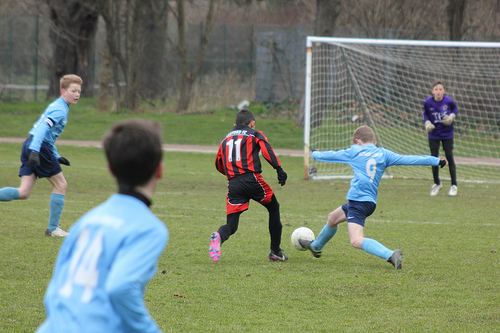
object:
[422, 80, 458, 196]
boy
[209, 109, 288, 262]
boy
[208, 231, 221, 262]
sole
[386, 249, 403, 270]
sole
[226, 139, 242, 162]
number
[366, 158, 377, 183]
number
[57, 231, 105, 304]
number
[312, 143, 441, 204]
jersey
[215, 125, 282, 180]
jersey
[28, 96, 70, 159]
jersey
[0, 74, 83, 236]
player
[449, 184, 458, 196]
shoe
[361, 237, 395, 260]
blue socks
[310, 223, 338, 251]
blue socks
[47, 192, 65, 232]
blue socks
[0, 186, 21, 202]
blue socks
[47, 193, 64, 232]
socks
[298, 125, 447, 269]
player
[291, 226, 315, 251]
ball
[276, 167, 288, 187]
gloves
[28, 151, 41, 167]
glove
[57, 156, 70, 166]
glove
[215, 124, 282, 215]
uniform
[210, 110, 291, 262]
player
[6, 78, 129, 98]
pond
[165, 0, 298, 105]
trees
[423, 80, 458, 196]
soccer player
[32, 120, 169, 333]
soccer player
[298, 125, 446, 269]
boy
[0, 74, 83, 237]
boy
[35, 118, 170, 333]
boy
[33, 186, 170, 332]
uniform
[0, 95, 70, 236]
uniform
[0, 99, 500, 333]
boys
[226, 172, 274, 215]
shorts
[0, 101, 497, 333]
field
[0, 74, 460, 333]
children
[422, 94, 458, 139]
jersey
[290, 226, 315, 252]
soccer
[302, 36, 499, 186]
netting